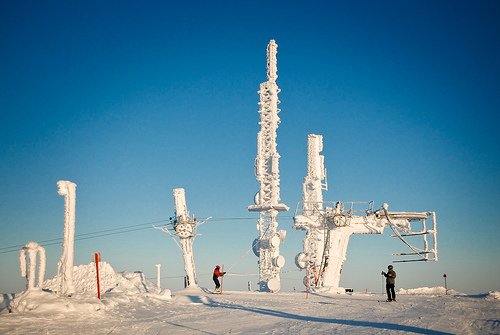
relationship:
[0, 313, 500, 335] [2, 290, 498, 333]
shadow falling on ground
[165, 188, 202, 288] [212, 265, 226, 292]
structure behind people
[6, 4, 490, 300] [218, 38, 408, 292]
air connected to structures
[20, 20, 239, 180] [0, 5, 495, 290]
patch of sky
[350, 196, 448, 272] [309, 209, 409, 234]
lift covered in ice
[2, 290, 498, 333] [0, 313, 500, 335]
ground full of shadow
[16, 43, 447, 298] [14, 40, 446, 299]
items covered with snow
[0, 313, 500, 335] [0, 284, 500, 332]
shadow covering ground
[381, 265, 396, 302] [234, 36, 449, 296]
man skiing by items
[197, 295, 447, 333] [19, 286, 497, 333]
shadow on ground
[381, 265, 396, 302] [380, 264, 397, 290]
man wearing coat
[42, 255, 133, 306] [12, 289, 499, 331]
pile of snow